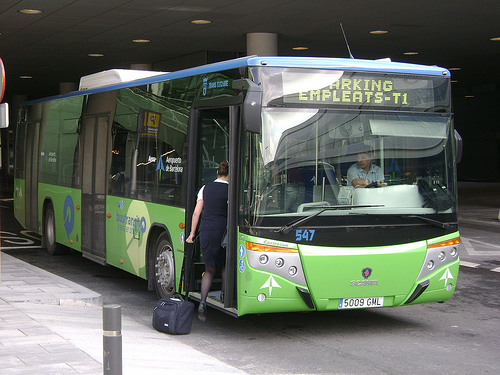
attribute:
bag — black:
[150, 292, 197, 337]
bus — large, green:
[17, 53, 494, 328]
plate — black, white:
[339, 289, 404, 317]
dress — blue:
[196, 182, 226, 264]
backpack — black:
[413, 175, 452, 214]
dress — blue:
[197, 179, 231, 264]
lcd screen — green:
[294, 72, 412, 111]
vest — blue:
[203, 178, 232, 241]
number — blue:
[296, 228, 316, 243]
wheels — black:
[36, 193, 185, 311]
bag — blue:
[141, 293, 201, 345]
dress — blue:
[182, 182, 243, 262]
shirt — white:
[189, 185, 238, 213]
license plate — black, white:
[336, 291, 381, 313]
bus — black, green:
[5, 50, 462, 327]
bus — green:
[32, 74, 322, 203]